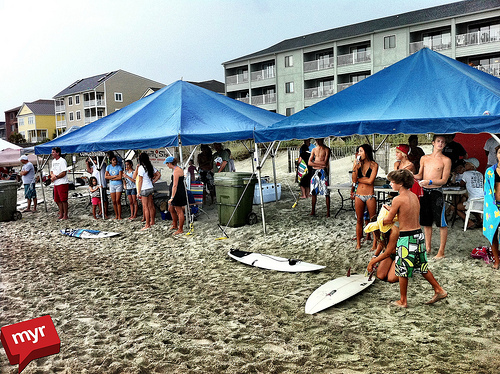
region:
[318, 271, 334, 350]
The surfboard is white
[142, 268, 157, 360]
The sand is very fine here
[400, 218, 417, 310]
This boy is wearing multi-colored trunks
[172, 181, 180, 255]
This person is wearing a black dress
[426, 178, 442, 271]
This person is wearing black trunks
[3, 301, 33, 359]
The letters myr are visible here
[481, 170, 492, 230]
This person is holding a light aqua towel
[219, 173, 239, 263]
there is a wast receptacle here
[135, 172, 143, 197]
This person has a white t-shirt on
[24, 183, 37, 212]
This man is wearing a pair of trunks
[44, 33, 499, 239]
Two large blue tents on a beach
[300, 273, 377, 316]
A white surfboard on the sand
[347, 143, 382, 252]
A woman in a bikini standing by a tent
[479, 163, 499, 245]
Part of a blue and yellow beach towel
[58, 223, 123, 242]
A blue and white surfboard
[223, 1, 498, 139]
An apartment building on a beach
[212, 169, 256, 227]
A stack of green bins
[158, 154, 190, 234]
A woman in black dress and blue baseball cap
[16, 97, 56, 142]
A yellow beach house with two windows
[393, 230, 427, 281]
Green, yellow and white swim trunks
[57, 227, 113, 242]
the white surfboard in the sand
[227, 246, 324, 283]
the white surfboard in the sand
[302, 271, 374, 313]
the white surfboard in the sand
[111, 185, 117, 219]
the leg of the woman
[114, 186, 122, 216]
the leg of the woman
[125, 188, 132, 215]
the leg of the woman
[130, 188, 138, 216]
the leg of the woman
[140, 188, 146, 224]
the leg of the woman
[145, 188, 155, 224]
the leg of the woman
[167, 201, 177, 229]
the leg of the woman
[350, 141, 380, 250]
woman in black and white bathing suit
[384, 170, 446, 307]
boy in black, yellow, and green swim trunks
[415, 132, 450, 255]
man in black and blue swim trunks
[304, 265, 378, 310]
white and black surfboard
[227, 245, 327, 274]
white and black surfboard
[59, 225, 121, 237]
white and black surfboard with blue towel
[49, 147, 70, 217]
man in white shirt and red trunks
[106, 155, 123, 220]
girl in blue shirt and white shorts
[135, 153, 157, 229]
girl in white shirt and gray shorts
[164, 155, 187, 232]
woman in black bathing suit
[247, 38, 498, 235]
blue tent on right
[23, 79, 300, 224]
blue tent on left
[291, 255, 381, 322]
surfboard is upside down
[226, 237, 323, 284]
surfboard lying in sand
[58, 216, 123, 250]
surfboard is blue and white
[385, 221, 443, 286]
boy wearing abstract swimming shorts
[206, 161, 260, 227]
large garbage can between tents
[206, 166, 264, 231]
large garbage can is green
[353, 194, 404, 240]
woman wearing yellow hat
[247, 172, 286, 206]
large white cooler in sand